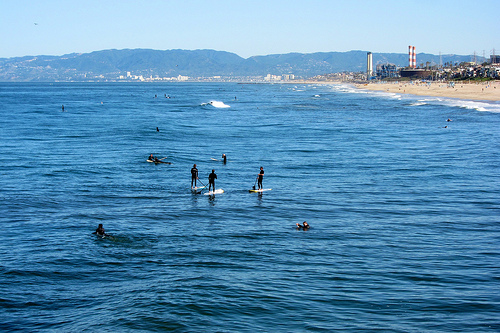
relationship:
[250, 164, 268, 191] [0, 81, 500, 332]
person paddle boarding on blue water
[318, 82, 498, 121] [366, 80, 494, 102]
waves forming near shore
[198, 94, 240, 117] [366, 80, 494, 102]
waves forming near shore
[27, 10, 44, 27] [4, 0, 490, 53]
plane flying through air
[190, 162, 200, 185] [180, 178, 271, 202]
person on boats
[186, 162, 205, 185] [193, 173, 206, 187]
person holding paddle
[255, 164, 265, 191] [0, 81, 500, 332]
person in blue water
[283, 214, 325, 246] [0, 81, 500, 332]
person in blue water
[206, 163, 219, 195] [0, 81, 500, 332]
person in blue water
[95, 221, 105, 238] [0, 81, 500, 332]
person in blue water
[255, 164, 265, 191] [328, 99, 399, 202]
person in ocean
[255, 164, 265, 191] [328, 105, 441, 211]
person in ocean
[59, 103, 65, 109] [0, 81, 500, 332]
person in blue water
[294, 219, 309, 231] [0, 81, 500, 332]
person in blue water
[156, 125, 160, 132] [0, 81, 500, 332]
person in blue water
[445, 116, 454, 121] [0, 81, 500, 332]
person in blue water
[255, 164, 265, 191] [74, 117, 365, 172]
person in ocean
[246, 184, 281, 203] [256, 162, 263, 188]
board under person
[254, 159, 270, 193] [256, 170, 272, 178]
paddle in hands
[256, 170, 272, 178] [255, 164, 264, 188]
hands of person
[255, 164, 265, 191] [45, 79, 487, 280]
person in ocean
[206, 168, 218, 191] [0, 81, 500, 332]
person in blue water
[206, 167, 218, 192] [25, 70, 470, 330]
person in ocean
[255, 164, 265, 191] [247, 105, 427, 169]
person in ocean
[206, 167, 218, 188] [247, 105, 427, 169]
person in ocean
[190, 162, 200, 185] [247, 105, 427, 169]
person in ocean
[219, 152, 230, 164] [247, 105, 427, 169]
person in ocean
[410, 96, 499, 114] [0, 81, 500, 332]
waves are in blue water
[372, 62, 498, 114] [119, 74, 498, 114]
people are in beach